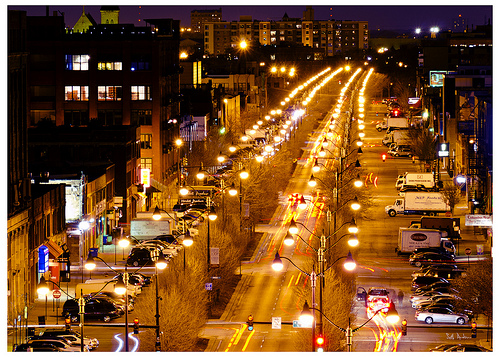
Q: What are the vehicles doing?
A: Parked.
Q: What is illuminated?
A: Lights.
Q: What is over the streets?
A: Lights.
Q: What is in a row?
A: Street lights.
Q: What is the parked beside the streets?
A: Vehicles.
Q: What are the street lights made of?
A: Metal.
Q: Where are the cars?
A: Parked on the sides of the street.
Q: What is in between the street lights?
A: The street.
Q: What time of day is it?
A: Night.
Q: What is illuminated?
A: The street lights and car lights.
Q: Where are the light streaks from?
A: Car lights being taken at long exposure.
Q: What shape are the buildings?
A: Rectangular.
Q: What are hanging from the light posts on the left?
A: White signs.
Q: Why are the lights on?
A: It is dark.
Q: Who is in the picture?
A: A person.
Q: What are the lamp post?
A: Lights.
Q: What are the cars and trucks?
A: Vehicles.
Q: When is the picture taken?
A: Nighttime.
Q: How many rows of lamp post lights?
A: Four.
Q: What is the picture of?
A: A city.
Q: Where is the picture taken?
A: In a metropolitan area.